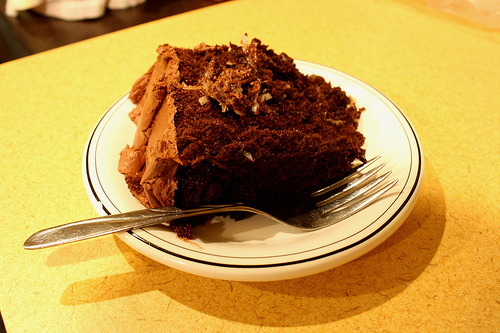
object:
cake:
[117, 32, 367, 240]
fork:
[22, 154, 400, 250]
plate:
[81, 60, 425, 281]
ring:
[85, 59, 422, 268]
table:
[0, 0, 500, 332]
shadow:
[114, 155, 446, 327]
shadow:
[60, 233, 160, 306]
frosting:
[117, 43, 181, 210]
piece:
[198, 94, 211, 105]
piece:
[259, 91, 273, 103]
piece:
[240, 33, 249, 50]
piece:
[241, 149, 254, 162]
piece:
[219, 102, 228, 112]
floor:
[0, 0, 231, 65]